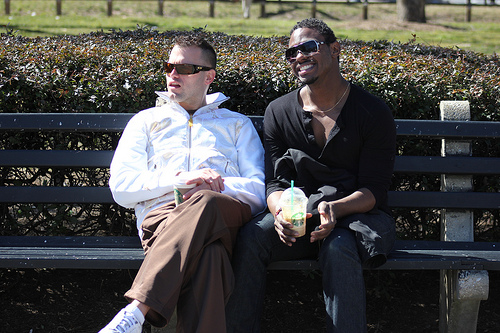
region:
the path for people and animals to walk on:
[0, 10, 497, 54]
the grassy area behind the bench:
[10, 35, 495, 237]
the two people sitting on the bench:
[96, 20, 396, 330]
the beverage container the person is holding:
[275, 176, 311, 238]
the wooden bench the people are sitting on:
[4, 98, 499, 329]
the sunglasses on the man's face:
[155, 56, 212, 79]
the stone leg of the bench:
[438, 97, 488, 326]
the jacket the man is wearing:
[108, 88, 269, 215]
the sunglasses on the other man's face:
[277, 39, 325, 61]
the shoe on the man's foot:
[96, 303, 141, 331]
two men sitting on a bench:
[100, 18, 397, 331]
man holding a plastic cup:
[278, 178, 308, 240]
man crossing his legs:
[128, 190, 248, 330]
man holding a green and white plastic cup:
[173, 183, 198, 208]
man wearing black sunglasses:
[160, 59, 214, 75]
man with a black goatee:
[293, 58, 322, 87]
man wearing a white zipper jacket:
[108, 90, 268, 215]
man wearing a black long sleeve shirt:
[261, 80, 393, 214]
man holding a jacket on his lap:
[272, 147, 399, 271]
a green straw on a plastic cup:
[288, 177, 297, 204]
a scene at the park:
[3, 0, 498, 329]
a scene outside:
[2, 3, 498, 317]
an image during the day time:
[2, 3, 499, 331]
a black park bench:
[1, 98, 498, 328]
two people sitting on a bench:
[0, 15, 498, 331]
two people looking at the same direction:
[85, 18, 397, 332]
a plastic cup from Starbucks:
[272, 179, 312, 246]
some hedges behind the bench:
[1, 25, 496, 115]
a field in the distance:
[2, 10, 497, 42]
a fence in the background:
[5, 0, 496, 22]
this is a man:
[283, 13, 360, 268]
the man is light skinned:
[186, 79, 208, 102]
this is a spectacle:
[273, 37, 317, 62]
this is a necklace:
[314, 94, 344, 124]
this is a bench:
[422, 102, 465, 286]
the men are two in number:
[120, 31, 385, 254]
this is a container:
[278, 183, 308, 228]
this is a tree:
[388, 40, 429, 89]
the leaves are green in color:
[410, 52, 438, 82]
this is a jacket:
[358, 224, 409, 255]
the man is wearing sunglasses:
[162, 60, 212, 77]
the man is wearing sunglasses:
[282, 40, 326, 57]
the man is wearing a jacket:
[111, 88, 266, 222]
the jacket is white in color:
[116, 90, 262, 205]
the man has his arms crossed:
[112, 103, 263, 201]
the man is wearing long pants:
[136, 185, 253, 325]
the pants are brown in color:
[136, 193, 266, 328]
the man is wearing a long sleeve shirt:
[267, 80, 390, 211]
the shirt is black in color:
[256, 83, 396, 219]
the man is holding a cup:
[273, 176, 314, 243]